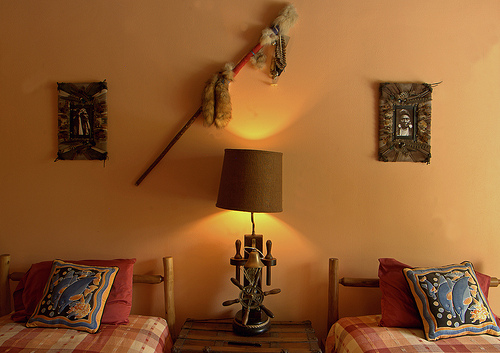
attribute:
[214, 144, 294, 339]
lamp — turned on, nautical themed, brown, on, decorative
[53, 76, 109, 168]
photograph — indian, covered in feathers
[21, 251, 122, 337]
pillow — designed, orange, red, brown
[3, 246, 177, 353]
bed — wooden, checkered, narrow, plaid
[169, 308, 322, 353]
end table — wooden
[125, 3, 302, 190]
weapon — indian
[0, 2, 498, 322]
wall — orange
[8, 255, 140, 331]
pillow — red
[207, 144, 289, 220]
shade — brown